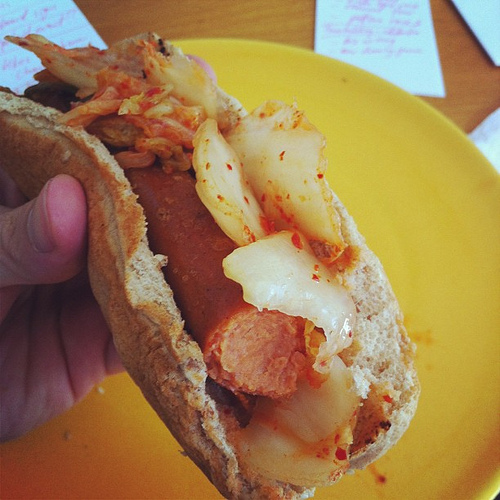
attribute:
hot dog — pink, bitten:
[1, 42, 409, 473]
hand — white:
[1, 182, 124, 442]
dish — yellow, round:
[222, 38, 498, 344]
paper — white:
[337, 0, 444, 89]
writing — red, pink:
[342, 8, 425, 57]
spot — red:
[363, 467, 394, 489]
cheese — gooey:
[30, 23, 163, 108]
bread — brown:
[94, 210, 192, 406]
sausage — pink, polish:
[211, 302, 301, 388]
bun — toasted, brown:
[154, 313, 388, 471]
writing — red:
[1, 8, 35, 24]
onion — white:
[169, 77, 312, 297]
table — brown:
[3, 0, 498, 131]